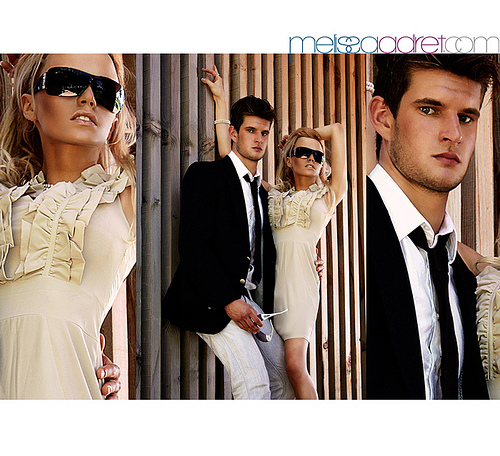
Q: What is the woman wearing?
A: A beige dress.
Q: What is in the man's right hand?
A: Sunglasses.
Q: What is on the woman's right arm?
A: A bracelet.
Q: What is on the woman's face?
A: Sunglasses.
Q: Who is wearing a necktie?
A: The man.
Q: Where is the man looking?
A: Into the camera.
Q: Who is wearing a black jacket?
A: The man.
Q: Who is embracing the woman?
A: The man.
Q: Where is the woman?
A: Next to the man.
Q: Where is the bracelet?
A: Woman's right wrist.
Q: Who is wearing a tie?
A: The man.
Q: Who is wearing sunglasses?
A: The woman.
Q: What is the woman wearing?
A: Dress.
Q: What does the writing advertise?
A: Website.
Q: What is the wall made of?
A: Wood.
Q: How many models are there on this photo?
A: 2.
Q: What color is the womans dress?
A: Cream.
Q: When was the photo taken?
A: Daytime.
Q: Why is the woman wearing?
A: Sunglasses.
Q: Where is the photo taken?
A: In front of wood panels.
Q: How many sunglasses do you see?
A: 3.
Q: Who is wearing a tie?
A: The male model.